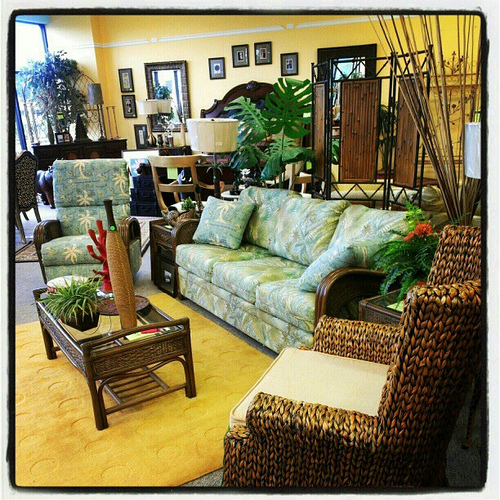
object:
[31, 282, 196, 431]
table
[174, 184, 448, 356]
couch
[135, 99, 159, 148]
lamp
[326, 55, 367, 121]
mirror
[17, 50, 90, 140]
plant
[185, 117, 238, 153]
lamp shade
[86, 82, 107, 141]
lamp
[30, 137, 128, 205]
dresser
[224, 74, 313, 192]
palm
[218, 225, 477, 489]
chair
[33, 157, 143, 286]
chair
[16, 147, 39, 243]
chair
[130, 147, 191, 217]
chair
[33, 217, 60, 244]
arms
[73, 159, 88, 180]
palm tree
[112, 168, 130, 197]
palm tree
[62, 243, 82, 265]
palm tree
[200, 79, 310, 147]
headboard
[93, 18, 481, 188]
wall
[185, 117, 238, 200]
lamp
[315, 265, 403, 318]
rattan arm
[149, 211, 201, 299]
side table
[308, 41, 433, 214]
bamboo divider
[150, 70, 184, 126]
framed mirror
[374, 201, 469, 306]
plant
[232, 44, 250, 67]
picture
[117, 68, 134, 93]
pictures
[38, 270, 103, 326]
plant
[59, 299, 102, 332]
planter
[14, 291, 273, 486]
rug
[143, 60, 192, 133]
frame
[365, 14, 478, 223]
sticks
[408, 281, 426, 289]
vase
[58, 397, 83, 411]
circle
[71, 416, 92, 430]
circle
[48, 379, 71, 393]
circle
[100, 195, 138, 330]
decoration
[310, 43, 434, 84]
frame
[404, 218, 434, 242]
flower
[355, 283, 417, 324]
table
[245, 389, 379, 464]
rattan arm